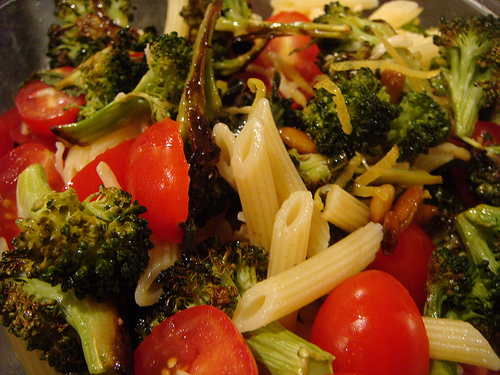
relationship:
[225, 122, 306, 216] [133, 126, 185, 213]
pasta with tomato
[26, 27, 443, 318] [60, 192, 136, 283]
salad has broccoli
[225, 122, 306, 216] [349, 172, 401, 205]
pasta has cheese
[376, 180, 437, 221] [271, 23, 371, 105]
bean under vegetable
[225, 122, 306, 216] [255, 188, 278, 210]
pasta has lines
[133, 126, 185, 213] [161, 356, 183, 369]
tomato has seeds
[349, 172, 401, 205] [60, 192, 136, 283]
cheese on broccoli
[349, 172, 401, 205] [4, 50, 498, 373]
cheese in salad